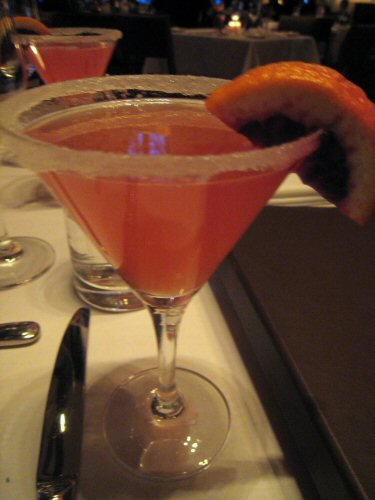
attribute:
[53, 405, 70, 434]
reflection — light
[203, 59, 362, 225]
slice — blood orange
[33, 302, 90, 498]
knife — silver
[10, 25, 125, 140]
drink — another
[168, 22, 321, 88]
table — another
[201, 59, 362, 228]
fruit — sliced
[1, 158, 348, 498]
table cloth — white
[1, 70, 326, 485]
martini — full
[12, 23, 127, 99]
martini — full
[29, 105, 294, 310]
cocktail — pink